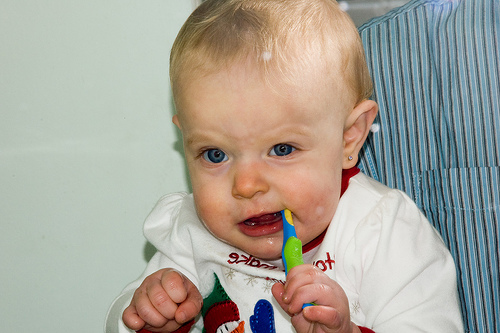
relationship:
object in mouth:
[280, 209, 315, 309] [237, 210, 285, 236]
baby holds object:
[105, 0, 463, 331] [280, 209, 317, 310]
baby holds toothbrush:
[105, 0, 463, 331] [278, 209, 308, 316]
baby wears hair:
[105, 0, 463, 331] [168, 0, 375, 102]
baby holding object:
[105, 0, 463, 331] [280, 209, 317, 310]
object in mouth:
[280, 209, 317, 310] [233, 205, 294, 238]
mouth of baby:
[233, 205, 294, 238] [105, 0, 463, 331]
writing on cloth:
[225, 249, 285, 280] [328, 207, 432, 329]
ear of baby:
[341, 96, 379, 172] [105, 0, 463, 331]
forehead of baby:
[176, 76, 303, 131] [105, 0, 463, 331]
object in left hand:
[280, 209, 317, 310] [271, 264, 354, 331]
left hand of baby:
[271, 264, 354, 331] [105, 0, 463, 331]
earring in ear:
[344, 151, 354, 164] [341, 96, 379, 172]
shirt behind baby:
[352, 0, 499, 331] [105, 0, 463, 331]